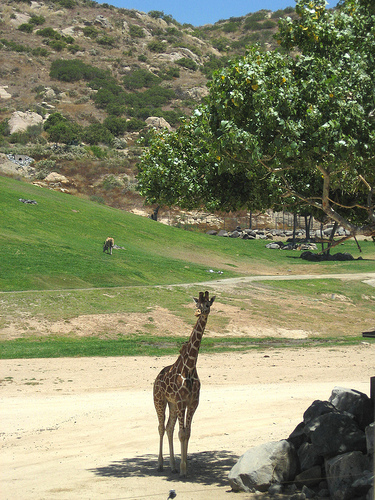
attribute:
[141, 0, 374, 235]
tree — large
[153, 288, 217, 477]
giraffe — head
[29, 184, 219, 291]
grass — green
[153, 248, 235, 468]
giraffe — long, brown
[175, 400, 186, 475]
leg — white 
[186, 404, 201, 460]
leg — long, brown, white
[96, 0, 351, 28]
sky — blue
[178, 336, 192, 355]
spot — brown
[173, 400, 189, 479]
leg — white, brown, long